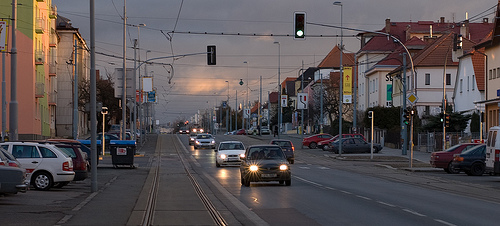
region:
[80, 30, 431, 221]
these cars are in a line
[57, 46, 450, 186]
this is an urban area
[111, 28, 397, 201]
this is a street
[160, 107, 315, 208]
the headlights are glowing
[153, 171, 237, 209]
these are train tracks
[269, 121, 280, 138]
a person standing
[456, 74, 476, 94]
windows of the building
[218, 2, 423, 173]
light posts on the side of the road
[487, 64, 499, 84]
windows of the building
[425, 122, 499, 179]
vehicles parked on the side of the road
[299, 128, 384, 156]
vehicles parked on the side of the road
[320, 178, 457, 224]
broken lines on the road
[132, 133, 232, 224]
railroad tracks on the ground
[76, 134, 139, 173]
trash bins on the side of the road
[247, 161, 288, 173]
lights of the car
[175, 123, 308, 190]
cars on the road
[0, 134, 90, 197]
cars parked on the side of the road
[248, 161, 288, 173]
headlights of the car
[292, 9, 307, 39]
a traffic light is green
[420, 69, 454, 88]
windows of the house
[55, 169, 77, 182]
bumper of the car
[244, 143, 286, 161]
a windshield of the car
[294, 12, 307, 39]
green traffic light lit above street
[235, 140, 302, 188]
silver car with headlights lit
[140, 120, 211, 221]
trolley tracks in concrete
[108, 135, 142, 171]
blue topped refuse bin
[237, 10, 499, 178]
row of red roofed buildings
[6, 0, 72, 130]
pink and green building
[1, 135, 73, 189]
white car parked near pink building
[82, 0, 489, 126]
cloudy blue sky with pink undertones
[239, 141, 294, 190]
grey car with lit headlights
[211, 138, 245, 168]
white car with lit headlights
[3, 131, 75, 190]
white car parked on side of street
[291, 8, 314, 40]
green traffic light lit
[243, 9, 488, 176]
row of red roofs and houses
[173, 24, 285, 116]
pink clouds in grey sky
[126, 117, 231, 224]
trolley tracks next to street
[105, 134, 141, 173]
blue and brown refuse bin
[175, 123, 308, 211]
row of cars on street with headlights lit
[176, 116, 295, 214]
row of cars with headlights lit on street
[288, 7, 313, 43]
traffic light indicating green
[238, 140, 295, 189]
silver car with headlights on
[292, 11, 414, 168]
traffic signal on metal pole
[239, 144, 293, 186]
headlights on dark car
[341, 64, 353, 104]
red arrow on yellow and white sign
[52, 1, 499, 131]
sky is gray and stormy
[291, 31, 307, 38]
a green light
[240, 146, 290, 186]
a car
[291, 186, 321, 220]
the street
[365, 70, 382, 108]
a house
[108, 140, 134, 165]
a trash can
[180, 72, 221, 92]
light in the sky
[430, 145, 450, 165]
a red car parked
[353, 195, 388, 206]
white line in the street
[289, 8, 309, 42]
green lit traffic signal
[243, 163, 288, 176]
lit white car headlights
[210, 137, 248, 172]
small white car on street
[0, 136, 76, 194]
rear side of white car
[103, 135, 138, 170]
blue bin at street side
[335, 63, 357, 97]
red and yellow sign